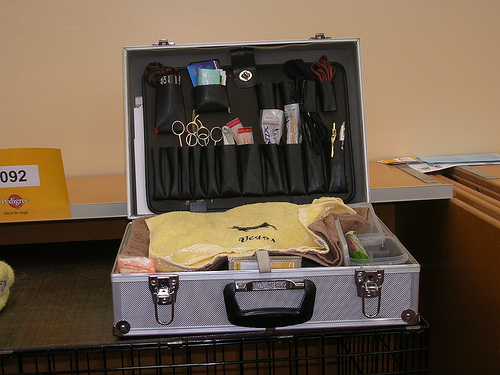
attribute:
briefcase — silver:
[124, 66, 428, 313]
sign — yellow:
[1, 140, 76, 225]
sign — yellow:
[6, 142, 92, 263]